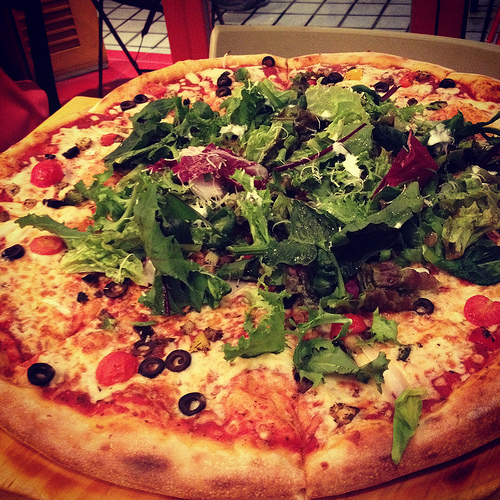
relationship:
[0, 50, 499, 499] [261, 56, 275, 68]
pizza has olive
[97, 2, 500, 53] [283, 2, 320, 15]
floor has tile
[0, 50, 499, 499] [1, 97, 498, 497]
pizza on top of board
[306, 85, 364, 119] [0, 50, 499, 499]
leaf on top of pizza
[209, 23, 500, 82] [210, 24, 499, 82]
chair has top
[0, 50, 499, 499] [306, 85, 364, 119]
pizza has leaf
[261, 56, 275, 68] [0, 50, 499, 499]
olive on top of pizza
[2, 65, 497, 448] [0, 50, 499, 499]
cheese on top of pizza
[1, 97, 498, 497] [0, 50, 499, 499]
board below pizza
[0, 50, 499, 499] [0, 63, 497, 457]
pizza has sauce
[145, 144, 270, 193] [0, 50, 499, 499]
salad on top of pizza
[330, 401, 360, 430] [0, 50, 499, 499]
mushroom on top of pizza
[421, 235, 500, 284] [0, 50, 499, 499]
spinach on top of pizza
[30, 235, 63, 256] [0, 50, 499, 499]
pepperoni on top of pizza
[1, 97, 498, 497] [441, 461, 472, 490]
board has knot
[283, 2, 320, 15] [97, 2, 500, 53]
tile on top of floor